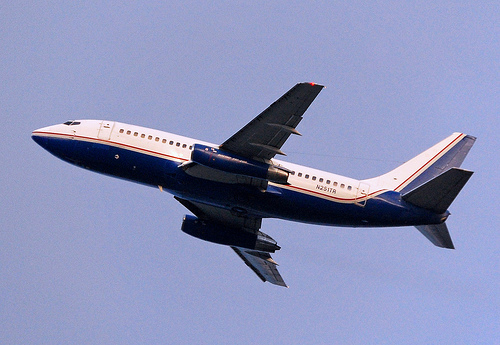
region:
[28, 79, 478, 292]
Airplane with a red stripe on it.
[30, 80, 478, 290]
Airplane colored blue on the bottom.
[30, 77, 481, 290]
Airplane with two wings.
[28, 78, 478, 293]
Airplane with windows on the sides.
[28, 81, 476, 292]
Airplane colored white on top.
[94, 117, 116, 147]
Door on a airplane.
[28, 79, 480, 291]
Airplane flying in the air.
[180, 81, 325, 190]
Wing of an airplane.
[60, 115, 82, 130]
Window on front of a plane.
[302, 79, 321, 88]
Red light on the wing of an airplane.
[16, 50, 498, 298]
a plane in the sky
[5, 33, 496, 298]
a plane in the sky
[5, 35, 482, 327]
a plane in the sky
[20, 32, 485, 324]
a plane in the sky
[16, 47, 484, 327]
a plane in the sky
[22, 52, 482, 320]
the plane is flying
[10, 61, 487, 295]
the plane is flying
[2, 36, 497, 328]
the plane is flying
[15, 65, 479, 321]
the plane is flying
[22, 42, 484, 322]
the plane is flying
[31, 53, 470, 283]
an airplane flying through the sky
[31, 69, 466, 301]
a plane flying in midair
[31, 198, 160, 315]
clear blue skies over the plane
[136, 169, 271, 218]
the blue belly of the plane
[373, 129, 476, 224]
blue and white tail fin of the pane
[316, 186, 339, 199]
black lettering on the side of the plane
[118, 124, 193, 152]
windows on the side of the plane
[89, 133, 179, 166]
red stripe on the side of the plane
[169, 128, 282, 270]
blue twin engines of the plane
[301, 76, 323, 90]
red light on the tip of the plane's wing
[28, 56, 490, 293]
this is a passenger jet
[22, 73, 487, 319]
the plane is ascending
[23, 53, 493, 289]
the plane is in the sky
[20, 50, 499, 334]
the plane is white and blue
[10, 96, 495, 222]
the plane has a red stripe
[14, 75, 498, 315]
the underside of the plane is blue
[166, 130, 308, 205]
this is an engine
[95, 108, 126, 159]
this is the door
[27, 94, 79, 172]
this is the cockpit and nose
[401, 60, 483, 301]
these are the tail fins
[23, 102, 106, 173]
front of a plane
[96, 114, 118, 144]
door of a plane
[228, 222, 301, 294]
wing of a plane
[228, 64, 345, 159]
wing of a plane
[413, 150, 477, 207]
wing of a plane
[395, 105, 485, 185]
wing of a plane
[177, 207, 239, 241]
turbine of a plane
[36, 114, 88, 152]
cockpit of a plane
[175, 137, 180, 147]
glass window on the airplane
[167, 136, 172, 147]
glass window on the airplane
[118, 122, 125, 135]
a window on a plane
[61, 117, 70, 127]
a window on a plane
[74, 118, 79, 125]
a window on a plane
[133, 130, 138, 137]
a window on a plane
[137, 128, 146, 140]
a window on a plane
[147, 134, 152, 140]
a window on a plane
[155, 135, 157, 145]
a window on a plane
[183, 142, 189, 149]
a window on a plane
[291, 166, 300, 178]
a window on a plane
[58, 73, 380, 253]
the airplane is blue and white